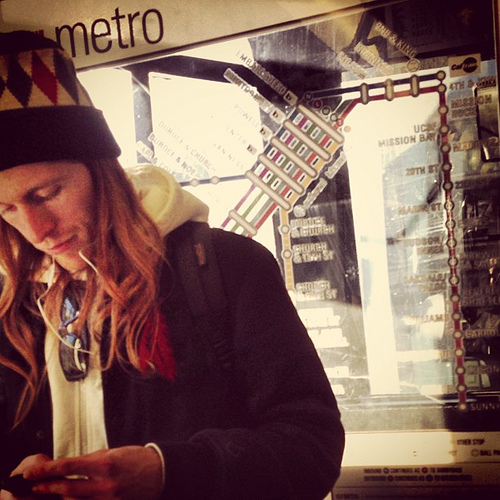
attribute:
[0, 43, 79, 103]
diamonds — red, black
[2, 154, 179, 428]
hair — long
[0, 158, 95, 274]
face — long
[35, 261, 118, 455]
sweatshirt — white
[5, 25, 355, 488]
man — red, wavy, left hand , nose 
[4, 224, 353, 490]
jacket — black, white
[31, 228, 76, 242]
mustache — short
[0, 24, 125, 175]
cap — knitted, knit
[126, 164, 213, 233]
hood — white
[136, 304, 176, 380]
hair — long, red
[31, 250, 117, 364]
wires — white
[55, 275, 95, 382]
sunglasses — dark, black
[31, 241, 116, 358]
headphone cords — white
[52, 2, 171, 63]
word — METRO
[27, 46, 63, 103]
diamond — red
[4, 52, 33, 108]
diamond — black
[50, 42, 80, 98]
diamond — black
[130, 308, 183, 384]
feathers — red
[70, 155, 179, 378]
hair — long, blonde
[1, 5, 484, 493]
subway — map , background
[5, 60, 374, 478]
man — patterned hat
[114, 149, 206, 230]
hoodie — mans , sunglasses 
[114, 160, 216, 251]
hoodie — white colored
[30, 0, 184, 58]
text — black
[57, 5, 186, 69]
text — METRO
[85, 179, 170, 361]
hair —  red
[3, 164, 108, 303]
face — man's 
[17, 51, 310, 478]
man — texting, looking down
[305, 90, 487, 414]
map — reflective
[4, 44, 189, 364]
man — long haired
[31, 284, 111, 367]
sunglasses — hanging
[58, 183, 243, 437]
hoodie — white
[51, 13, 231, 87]
lettering — black